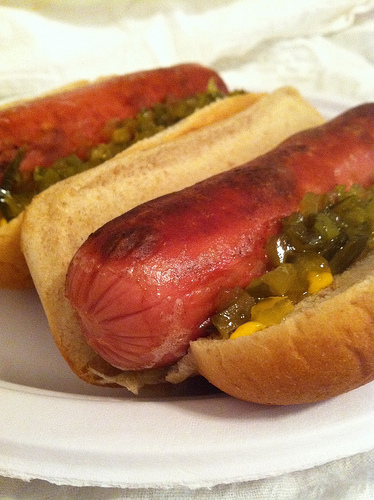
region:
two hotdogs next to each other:
[9, 39, 373, 393]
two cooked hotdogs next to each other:
[12, 34, 372, 408]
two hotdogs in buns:
[2, 49, 373, 469]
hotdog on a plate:
[45, 73, 373, 498]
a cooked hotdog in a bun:
[75, 97, 373, 400]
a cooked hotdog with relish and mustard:
[49, 92, 371, 412]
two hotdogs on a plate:
[29, 12, 368, 483]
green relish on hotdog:
[188, 162, 373, 330]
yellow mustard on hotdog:
[146, 152, 371, 369]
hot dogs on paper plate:
[9, 59, 360, 409]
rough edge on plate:
[44, 444, 351, 488]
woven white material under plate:
[212, 450, 364, 492]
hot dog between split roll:
[28, 98, 359, 389]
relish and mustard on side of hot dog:
[204, 174, 362, 342]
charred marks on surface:
[86, 130, 314, 267]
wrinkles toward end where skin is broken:
[59, 245, 162, 374]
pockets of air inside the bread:
[82, 130, 227, 198]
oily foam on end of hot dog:
[144, 282, 188, 374]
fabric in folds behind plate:
[36, 7, 370, 110]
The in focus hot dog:
[65, 100, 371, 373]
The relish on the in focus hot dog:
[212, 179, 372, 331]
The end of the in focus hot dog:
[60, 227, 180, 374]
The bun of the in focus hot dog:
[14, 82, 372, 405]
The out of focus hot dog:
[0, 58, 226, 190]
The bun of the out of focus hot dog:
[2, 75, 273, 291]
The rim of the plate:
[0, 360, 371, 487]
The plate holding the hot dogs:
[0, 276, 372, 490]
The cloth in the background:
[1, 1, 372, 120]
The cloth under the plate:
[1, 444, 373, 498]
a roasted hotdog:
[60, 99, 370, 370]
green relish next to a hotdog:
[206, 185, 369, 330]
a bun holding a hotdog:
[10, 84, 367, 395]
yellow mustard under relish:
[223, 264, 333, 346]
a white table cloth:
[4, 456, 366, 498]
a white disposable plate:
[0, 338, 371, 482]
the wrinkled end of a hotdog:
[62, 243, 175, 377]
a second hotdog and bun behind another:
[0, 59, 260, 276]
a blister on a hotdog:
[235, 130, 335, 216]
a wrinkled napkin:
[186, 4, 370, 65]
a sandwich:
[46, 127, 372, 418]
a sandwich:
[21, 78, 337, 328]